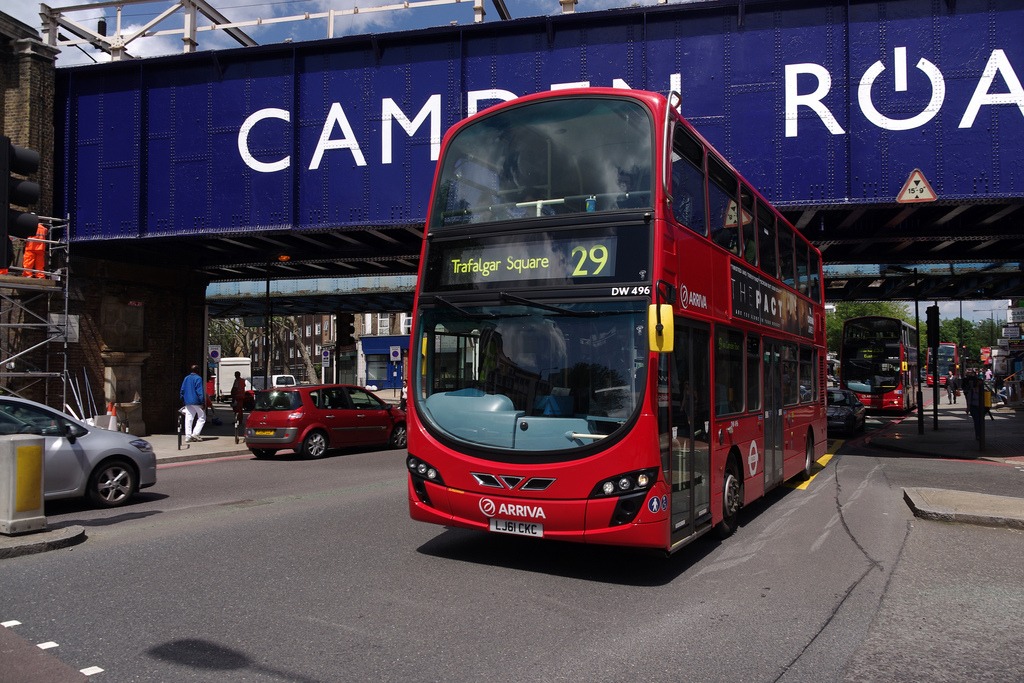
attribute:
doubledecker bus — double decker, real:
[397, 87, 831, 562]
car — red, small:
[248, 381, 394, 458]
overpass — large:
[55, 24, 1023, 253]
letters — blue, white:
[244, 28, 1023, 174]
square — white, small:
[4, 607, 24, 637]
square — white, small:
[34, 632, 66, 652]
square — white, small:
[74, 654, 110, 680]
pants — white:
[184, 402, 211, 440]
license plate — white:
[488, 517, 545, 538]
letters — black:
[488, 517, 545, 538]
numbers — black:
[488, 517, 545, 538]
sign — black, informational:
[428, 230, 618, 281]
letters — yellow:
[443, 249, 552, 281]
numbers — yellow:
[567, 243, 618, 281]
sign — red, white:
[892, 163, 941, 206]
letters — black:
[892, 163, 941, 206]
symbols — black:
[892, 163, 941, 206]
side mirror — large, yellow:
[646, 296, 678, 355]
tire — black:
[89, 454, 137, 500]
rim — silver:
[96, 464, 136, 500]